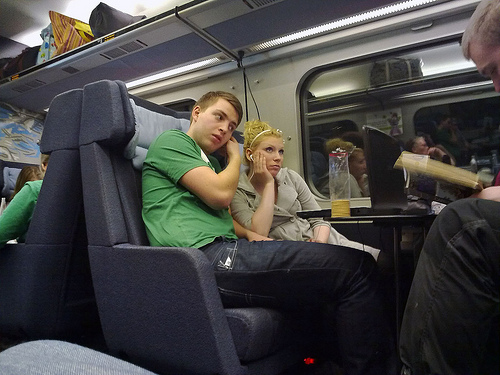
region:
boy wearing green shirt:
[136, 94, 238, 290]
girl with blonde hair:
[235, 119, 321, 236]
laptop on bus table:
[348, 126, 411, 208]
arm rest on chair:
[111, 229, 211, 291]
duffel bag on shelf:
[91, 0, 146, 29]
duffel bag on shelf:
[51, 12, 93, 46]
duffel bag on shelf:
[41, 26, 59, 59]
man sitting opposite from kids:
[436, 27, 498, 331]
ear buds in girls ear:
[243, 153, 255, 182]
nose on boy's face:
[213, 119, 230, 136]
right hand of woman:
[237, 148, 284, 184]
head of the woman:
[239, 104, 291, 183]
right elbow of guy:
[186, 160, 265, 226]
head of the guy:
[168, 77, 245, 147]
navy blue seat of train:
[67, 80, 235, 362]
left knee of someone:
[426, 180, 494, 278]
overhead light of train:
[260, 27, 402, 58]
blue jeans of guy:
[215, 252, 382, 337]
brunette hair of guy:
[194, 76, 256, 111]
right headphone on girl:
[242, 145, 259, 174]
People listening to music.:
[211, 129, 278, 233]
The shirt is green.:
[151, 141, 230, 253]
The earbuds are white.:
[234, 149, 264, 188]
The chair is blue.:
[29, 137, 189, 345]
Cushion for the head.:
[122, 98, 200, 167]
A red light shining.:
[282, 342, 332, 372]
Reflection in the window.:
[295, 82, 498, 199]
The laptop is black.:
[291, 123, 411, 213]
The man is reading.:
[378, 117, 499, 222]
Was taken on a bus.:
[5, 13, 498, 373]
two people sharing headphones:
[109, 72, 394, 349]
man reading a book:
[364, 1, 499, 338]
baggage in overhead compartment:
[5, 4, 167, 70]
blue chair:
[61, 80, 358, 371]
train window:
[273, 45, 495, 212]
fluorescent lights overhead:
[40, 0, 468, 109]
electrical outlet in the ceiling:
[221, 42, 263, 87]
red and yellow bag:
[36, 2, 102, 67]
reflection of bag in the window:
[343, 40, 453, 92]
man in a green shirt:
[138, 87, 393, 373]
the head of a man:
[186, 86, 242, 147]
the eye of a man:
[210, 105, 225, 120]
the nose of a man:
[215, 115, 230, 135]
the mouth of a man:
[205, 125, 222, 140]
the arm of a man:
[157, 125, 242, 206]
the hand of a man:
[220, 130, 241, 160]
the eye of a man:
[188, 101, 202, 122]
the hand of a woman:
[250, 145, 273, 182]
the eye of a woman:
[261, 142, 275, 154]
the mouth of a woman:
[266, 160, 283, 169]